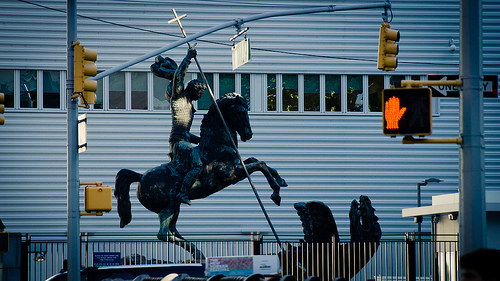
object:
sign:
[381, 88, 432, 137]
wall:
[79, 114, 421, 234]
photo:
[0, 0, 500, 281]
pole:
[66, 0, 79, 281]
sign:
[230, 27, 252, 71]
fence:
[20, 232, 455, 281]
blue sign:
[93, 252, 121, 267]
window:
[283, 74, 298, 111]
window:
[43, 70, 59, 108]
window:
[132, 72, 148, 109]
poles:
[20, 231, 458, 279]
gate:
[20, 232, 458, 281]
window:
[325, 75, 341, 112]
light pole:
[418, 183, 422, 277]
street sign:
[427, 74, 499, 99]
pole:
[459, 0, 489, 280]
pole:
[167, 7, 288, 255]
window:
[241, 73, 250, 111]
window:
[267, 74, 276, 111]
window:
[305, 75, 320, 111]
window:
[347, 75, 363, 113]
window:
[368, 75, 384, 112]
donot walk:
[382, 88, 432, 135]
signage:
[204, 255, 279, 278]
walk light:
[84, 187, 111, 212]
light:
[385, 96, 407, 129]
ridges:
[0, 0, 500, 241]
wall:
[1, 1, 498, 241]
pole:
[89, 1, 391, 81]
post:
[385, 95, 407, 129]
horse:
[114, 93, 287, 265]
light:
[377, 26, 399, 71]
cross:
[167, 8, 186, 38]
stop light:
[73, 40, 97, 109]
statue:
[113, 43, 289, 263]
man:
[164, 42, 207, 205]